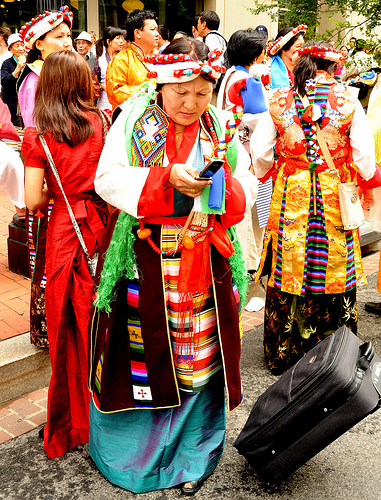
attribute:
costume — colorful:
[94, 106, 245, 487]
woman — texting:
[121, 32, 212, 137]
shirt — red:
[18, 119, 111, 217]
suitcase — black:
[235, 330, 379, 474]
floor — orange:
[3, 266, 37, 348]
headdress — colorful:
[10, 8, 102, 59]